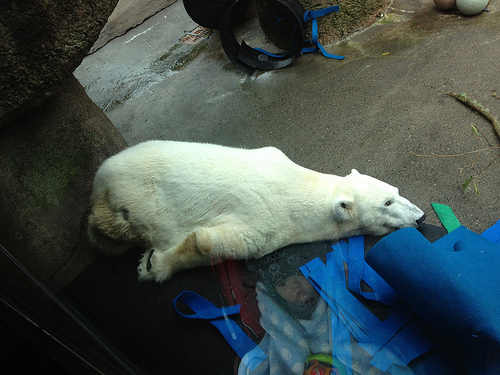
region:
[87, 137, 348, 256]
polar bear laying on ground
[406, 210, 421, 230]
polar bear with black nose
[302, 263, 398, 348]
blue strips of colored paper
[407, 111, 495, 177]
branch broken off tree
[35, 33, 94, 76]
dark gray top of habitat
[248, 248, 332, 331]
face of child in bandana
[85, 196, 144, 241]
dark spot on polar bear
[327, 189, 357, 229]
small ear of polar bear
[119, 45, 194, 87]
scarred floor of habitat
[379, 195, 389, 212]
polar bear with black eye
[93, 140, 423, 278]
A polar bear on the ground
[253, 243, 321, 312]
A child reflected in the window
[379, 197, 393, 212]
The right eye of the polar bear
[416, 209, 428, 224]
The nose of the polar bear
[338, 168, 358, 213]
The ears of the polar bear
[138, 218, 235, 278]
The leg of the polar bear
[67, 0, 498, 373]
The ground beneath the polar bear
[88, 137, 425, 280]
The polar bear is lying down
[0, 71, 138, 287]
A wall behind the polar bear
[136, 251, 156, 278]
The claws of the polar bear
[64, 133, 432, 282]
a white polar bear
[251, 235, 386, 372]
reflection of a baby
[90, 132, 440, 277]
white polar bear lying down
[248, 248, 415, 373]
baby in a blue blanket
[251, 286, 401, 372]
a blue and white blanket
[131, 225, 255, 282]
the arm of the polar bear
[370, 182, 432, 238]
the face of the polar bear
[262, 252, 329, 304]
the face of a baby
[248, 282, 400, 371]
a polkadotted baby blanket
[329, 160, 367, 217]
the white ears of the polar bear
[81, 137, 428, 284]
White bear laying on the ground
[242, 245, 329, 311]
Baby face image on the ground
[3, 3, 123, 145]
Dark brown tree trunk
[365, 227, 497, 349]
Dark blue fabric on the ground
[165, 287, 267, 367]
Dark blue piece of fabric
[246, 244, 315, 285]
Printed pattern baby's hat image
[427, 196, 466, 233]
Green piece of fabric laying down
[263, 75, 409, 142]
Stone hard surface ground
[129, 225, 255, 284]
White bear right extremity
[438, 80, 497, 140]
Piece of wood stick on the ground